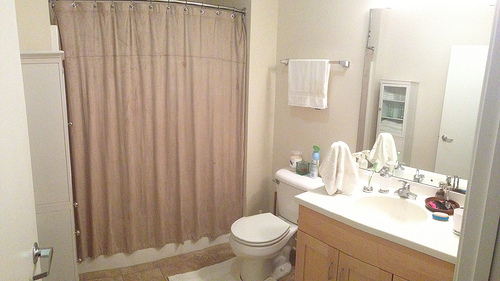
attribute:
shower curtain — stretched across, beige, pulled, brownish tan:
[50, 1, 249, 262]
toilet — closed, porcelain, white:
[220, 155, 322, 280]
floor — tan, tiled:
[66, 203, 352, 280]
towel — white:
[286, 58, 332, 111]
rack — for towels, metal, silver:
[280, 55, 352, 71]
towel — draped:
[320, 141, 360, 198]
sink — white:
[292, 161, 473, 279]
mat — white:
[167, 244, 297, 279]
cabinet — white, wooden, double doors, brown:
[289, 208, 456, 280]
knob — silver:
[438, 132, 454, 148]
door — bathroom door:
[432, 40, 489, 178]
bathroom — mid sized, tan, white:
[2, 2, 500, 280]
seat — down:
[227, 211, 287, 245]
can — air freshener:
[307, 142, 324, 180]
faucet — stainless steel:
[391, 176, 419, 203]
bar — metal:
[160, 1, 253, 14]